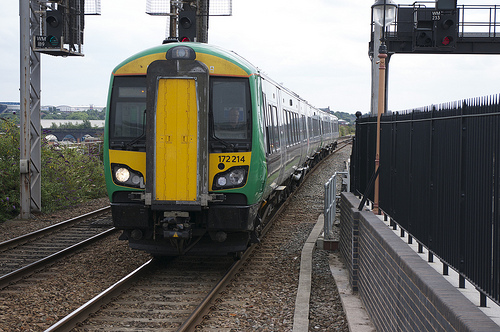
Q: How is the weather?
A: It is sunny.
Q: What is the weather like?
A: It is sunny.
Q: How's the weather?
A: It is sunny.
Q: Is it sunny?
A: Yes, it is sunny.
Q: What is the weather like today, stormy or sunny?
A: It is sunny.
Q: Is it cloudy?
A: No, it is sunny.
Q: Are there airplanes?
A: No, there are no airplanes.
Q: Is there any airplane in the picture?
A: No, there are no airplanes.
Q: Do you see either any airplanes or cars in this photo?
A: No, there are no airplanes or cars.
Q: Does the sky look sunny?
A: Yes, the sky is sunny.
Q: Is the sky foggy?
A: No, the sky is sunny.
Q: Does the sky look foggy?
A: No, the sky is sunny.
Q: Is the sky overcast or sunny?
A: The sky is sunny.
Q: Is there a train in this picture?
A: Yes, there is a train.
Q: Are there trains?
A: Yes, there is a train.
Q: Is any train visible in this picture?
A: Yes, there is a train.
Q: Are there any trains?
A: Yes, there is a train.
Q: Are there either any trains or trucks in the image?
A: Yes, there is a train.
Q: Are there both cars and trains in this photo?
A: No, there is a train but no cars.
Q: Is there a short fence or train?
A: Yes, there is a short train.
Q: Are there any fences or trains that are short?
A: Yes, the train is short.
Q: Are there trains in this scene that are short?
A: Yes, there is a short train.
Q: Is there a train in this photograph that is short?
A: Yes, there is a train that is short.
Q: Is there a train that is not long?
A: Yes, there is a short train.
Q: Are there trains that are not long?
A: Yes, there is a short train.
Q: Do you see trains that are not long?
A: Yes, there is a short train.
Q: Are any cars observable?
A: No, there are no cars.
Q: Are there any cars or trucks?
A: No, there are no cars or trucks.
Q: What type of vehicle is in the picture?
A: The vehicle is a train.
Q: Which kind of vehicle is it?
A: The vehicle is a train.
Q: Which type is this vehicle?
A: This is a train.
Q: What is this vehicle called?
A: This is a train.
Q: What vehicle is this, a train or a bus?
A: This is a train.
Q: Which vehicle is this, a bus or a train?
A: This is a train.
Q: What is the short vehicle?
A: The vehicle is a train.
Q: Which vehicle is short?
A: The vehicle is a train.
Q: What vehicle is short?
A: The vehicle is a train.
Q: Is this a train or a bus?
A: This is a train.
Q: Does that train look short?
A: Yes, the train is short.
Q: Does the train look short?
A: Yes, the train is short.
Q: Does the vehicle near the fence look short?
A: Yes, the train is short.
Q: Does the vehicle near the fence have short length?
A: Yes, the train is short.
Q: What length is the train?
A: The train is short.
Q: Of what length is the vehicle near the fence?
A: The train is short.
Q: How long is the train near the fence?
A: The train is short.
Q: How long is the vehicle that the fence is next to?
A: The train is short.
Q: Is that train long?
A: No, the train is short.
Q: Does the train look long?
A: No, the train is short.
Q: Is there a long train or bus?
A: No, there is a train but it is short.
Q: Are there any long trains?
A: No, there is a train but it is short.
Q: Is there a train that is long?
A: No, there is a train but it is short.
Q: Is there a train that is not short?
A: No, there is a train but it is short.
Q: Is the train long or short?
A: The train is short.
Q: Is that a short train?
A: Yes, that is a short train.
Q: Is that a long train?
A: No, that is a short train.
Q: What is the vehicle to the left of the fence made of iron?
A: The vehicle is a train.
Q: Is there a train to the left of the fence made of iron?
A: Yes, there is a train to the left of the fence.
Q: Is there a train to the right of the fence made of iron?
A: No, the train is to the left of the fence.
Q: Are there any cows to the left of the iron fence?
A: No, there is a train to the left of the fence.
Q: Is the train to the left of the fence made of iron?
A: Yes, the train is to the left of the fence.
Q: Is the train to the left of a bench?
A: No, the train is to the left of the fence.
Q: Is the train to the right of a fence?
A: No, the train is to the left of a fence.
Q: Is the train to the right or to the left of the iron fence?
A: The train is to the left of the fence.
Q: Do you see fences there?
A: Yes, there is a fence.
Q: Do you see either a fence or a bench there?
A: Yes, there is a fence.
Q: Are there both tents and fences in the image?
A: No, there is a fence but no tents.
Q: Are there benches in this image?
A: No, there are no benches.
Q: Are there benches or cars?
A: No, there are no benches or cars.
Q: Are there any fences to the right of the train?
A: Yes, there is a fence to the right of the train.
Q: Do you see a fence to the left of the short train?
A: No, the fence is to the right of the train.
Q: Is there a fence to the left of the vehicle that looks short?
A: No, the fence is to the right of the train.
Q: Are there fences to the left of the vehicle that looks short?
A: No, the fence is to the right of the train.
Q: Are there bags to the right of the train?
A: No, there is a fence to the right of the train.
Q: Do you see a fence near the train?
A: Yes, there is a fence near the train.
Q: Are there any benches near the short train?
A: No, there is a fence near the train.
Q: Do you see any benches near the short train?
A: No, there is a fence near the train.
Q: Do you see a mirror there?
A: No, there are no mirrors.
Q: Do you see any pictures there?
A: No, there are no pictures.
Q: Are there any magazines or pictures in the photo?
A: No, there are no pictures or magazines.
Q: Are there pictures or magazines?
A: No, there are no pictures or magazines.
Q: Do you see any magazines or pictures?
A: No, there are no pictures or magazines.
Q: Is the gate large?
A: Yes, the gate is large.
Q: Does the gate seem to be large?
A: Yes, the gate is large.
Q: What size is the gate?
A: The gate is large.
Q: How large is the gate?
A: The gate is large.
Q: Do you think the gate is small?
A: No, the gate is large.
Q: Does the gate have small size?
A: No, the gate is large.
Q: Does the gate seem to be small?
A: No, the gate is large.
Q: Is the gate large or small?
A: The gate is large.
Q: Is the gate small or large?
A: The gate is large.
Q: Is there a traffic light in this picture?
A: Yes, there is a traffic light.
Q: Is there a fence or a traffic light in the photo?
A: Yes, there is a traffic light.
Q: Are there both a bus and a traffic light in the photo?
A: No, there is a traffic light but no buses.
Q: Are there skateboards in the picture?
A: No, there are no skateboards.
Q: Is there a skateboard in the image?
A: No, there are no skateboards.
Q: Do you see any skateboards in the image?
A: No, there are no skateboards.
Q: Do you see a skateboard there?
A: No, there are no skateboards.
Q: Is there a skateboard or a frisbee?
A: No, there are no skateboards or frisbees.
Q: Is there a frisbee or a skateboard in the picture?
A: No, there are no skateboards or frisbees.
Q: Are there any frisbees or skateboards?
A: No, there are no skateboards or frisbees.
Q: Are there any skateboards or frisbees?
A: No, there are no skateboards or frisbees.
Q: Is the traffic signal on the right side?
A: Yes, the traffic signal is on the right of the image.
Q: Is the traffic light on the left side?
A: No, the traffic light is on the right of the image.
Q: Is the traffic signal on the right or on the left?
A: The traffic signal is on the right of the image.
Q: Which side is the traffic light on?
A: The traffic light is on the right of the image.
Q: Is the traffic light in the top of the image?
A: Yes, the traffic light is in the top of the image.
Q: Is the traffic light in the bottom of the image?
A: No, the traffic light is in the top of the image.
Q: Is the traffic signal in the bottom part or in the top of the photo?
A: The traffic signal is in the top of the image.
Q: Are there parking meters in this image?
A: No, there are no parking meters.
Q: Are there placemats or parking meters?
A: No, there are no parking meters or placemats.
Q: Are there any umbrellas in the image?
A: No, there are no umbrellas.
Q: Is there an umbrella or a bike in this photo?
A: No, there are no umbrellas or bikes.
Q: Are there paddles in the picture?
A: No, there are no paddles.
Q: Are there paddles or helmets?
A: No, there are no paddles or helmets.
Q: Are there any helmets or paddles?
A: No, there are no paddles or helmets.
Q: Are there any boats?
A: No, there are no boats.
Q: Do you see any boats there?
A: No, there are no boats.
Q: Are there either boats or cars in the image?
A: No, there are no boats or cars.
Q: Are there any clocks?
A: No, there are no clocks.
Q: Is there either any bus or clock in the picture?
A: No, there are no clocks or buses.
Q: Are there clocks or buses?
A: No, there are no clocks or buses.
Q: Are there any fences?
A: Yes, there is a fence.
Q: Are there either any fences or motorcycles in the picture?
A: Yes, there is a fence.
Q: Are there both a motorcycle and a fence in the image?
A: No, there is a fence but no motorcycles.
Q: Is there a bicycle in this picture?
A: No, there are no bicycles.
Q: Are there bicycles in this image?
A: No, there are no bicycles.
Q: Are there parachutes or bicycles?
A: No, there are no bicycles or parachutes.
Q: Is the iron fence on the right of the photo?
A: Yes, the fence is on the right of the image.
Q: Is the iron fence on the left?
A: No, the fence is on the right of the image.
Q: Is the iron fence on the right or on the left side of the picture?
A: The fence is on the right of the image.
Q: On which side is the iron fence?
A: The fence is on the right of the image.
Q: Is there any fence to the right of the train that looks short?
A: Yes, there is a fence to the right of the train.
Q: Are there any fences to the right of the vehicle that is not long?
A: Yes, there is a fence to the right of the train.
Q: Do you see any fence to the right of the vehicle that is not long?
A: Yes, there is a fence to the right of the train.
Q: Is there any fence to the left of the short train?
A: No, the fence is to the right of the train.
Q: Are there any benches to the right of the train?
A: No, there is a fence to the right of the train.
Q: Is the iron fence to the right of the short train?
A: Yes, the fence is to the right of the train.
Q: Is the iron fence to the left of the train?
A: No, the fence is to the right of the train.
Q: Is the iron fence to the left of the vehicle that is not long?
A: No, the fence is to the right of the train.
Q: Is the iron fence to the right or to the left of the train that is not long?
A: The fence is to the right of the train.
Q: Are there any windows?
A: Yes, there is a window.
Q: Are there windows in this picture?
A: Yes, there is a window.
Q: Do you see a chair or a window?
A: Yes, there is a window.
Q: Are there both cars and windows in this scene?
A: No, there is a window but no cars.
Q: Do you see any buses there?
A: No, there are no buses.